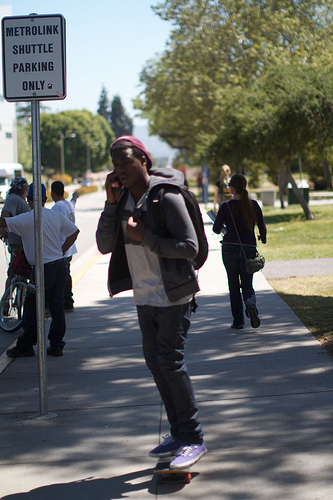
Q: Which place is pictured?
A: It is a sidewalk.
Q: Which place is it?
A: It is a sidewalk.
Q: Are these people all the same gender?
A: No, they are both male and female.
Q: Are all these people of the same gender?
A: No, they are both male and female.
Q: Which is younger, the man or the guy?
A: The man is younger than the guy.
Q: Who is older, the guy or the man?
A: The guy is older than the man.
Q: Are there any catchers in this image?
A: No, there are no catchers.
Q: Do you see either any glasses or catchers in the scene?
A: No, there are no catchers or glasses.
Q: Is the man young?
A: Yes, the man is young.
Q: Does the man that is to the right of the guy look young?
A: Yes, the man is young.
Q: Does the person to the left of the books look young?
A: Yes, the man is young.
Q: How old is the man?
A: The man is young.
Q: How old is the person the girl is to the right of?
A: The man is young.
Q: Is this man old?
A: No, the man is young.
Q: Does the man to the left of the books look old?
A: No, the man is young.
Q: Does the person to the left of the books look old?
A: No, the man is young.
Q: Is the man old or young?
A: The man is young.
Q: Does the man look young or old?
A: The man is young.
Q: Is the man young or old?
A: The man is young.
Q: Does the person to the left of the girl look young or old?
A: The man is young.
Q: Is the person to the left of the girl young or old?
A: The man is young.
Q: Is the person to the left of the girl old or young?
A: The man is young.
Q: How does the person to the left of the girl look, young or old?
A: The man is young.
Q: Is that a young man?
A: Yes, that is a young man.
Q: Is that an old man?
A: No, that is a young man.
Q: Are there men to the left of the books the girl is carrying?
A: Yes, there is a man to the left of the books.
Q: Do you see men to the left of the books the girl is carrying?
A: Yes, there is a man to the left of the books.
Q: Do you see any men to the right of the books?
A: No, the man is to the left of the books.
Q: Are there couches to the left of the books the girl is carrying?
A: No, there is a man to the left of the books.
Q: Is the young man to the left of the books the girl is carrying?
A: Yes, the man is to the left of the books.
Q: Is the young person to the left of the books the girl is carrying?
A: Yes, the man is to the left of the books.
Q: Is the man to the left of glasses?
A: No, the man is to the left of the books.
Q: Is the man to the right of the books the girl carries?
A: No, the man is to the left of the books.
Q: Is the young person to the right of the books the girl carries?
A: No, the man is to the left of the books.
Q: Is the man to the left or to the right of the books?
A: The man is to the left of the books.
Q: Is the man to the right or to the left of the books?
A: The man is to the left of the books.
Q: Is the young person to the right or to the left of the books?
A: The man is to the left of the books.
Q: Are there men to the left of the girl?
A: Yes, there is a man to the left of the girl.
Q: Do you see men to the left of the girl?
A: Yes, there is a man to the left of the girl.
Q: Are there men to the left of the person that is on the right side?
A: Yes, there is a man to the left of the girl.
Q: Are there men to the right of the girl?
A: No, the man is to the left of the girl.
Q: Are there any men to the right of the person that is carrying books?
A: No, the man is to the left of the girl.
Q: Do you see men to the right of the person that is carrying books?
A: No, the man is to the left of the girl.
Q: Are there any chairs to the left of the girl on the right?
A: No, there is a man to the left of the girl.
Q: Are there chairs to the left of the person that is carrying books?
A: No, there is a man to the left of the girl.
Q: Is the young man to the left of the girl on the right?
A: Yes, the man is to the left of the girl.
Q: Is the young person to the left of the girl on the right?
A: Yes, the man is to the left of the girl.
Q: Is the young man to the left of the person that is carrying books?
A: Yes, the man is to the left of the girl.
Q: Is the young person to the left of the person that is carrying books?
A: Yes, the man is to the left of the girl.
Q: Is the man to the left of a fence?
A: No, the man is to the left of the girl.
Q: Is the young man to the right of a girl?
A: No, the man is to the left of a girl.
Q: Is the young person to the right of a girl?
A: No, the man is to the left of a girl.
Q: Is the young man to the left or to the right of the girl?
A: The man is to the left of the girl.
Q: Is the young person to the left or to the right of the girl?
A: The man is to the left of the girl.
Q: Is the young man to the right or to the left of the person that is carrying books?
A: The man is to the left of the girl.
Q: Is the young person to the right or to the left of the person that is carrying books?
A: The man is to the left of the girl.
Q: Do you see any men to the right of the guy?
A: Yes, there is a man to the right of the guy.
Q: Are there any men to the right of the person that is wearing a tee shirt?
A: Yes, there is a man to the right of the guy.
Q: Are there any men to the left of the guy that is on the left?
A: No, the man is to the right of the guy.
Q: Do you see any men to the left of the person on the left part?
A: No, the man is to the right of the guy.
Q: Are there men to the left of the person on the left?
A: No, the man is to the right of the guy.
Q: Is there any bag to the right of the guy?
A: No, there is a man to the right of the guy.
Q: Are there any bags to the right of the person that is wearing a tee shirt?
A: No, there is a man to the right of the guy.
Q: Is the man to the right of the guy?
A: Yes, the man is to the right of the guy.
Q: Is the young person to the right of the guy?
A: Yes, the man is to the right of the guy.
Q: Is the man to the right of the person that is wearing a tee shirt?
A: Yes, the man is to the right of the guy.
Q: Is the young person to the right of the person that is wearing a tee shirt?
A: Yes, the man is to the right of the guy.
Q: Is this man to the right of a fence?
A: No, the man is to the right of the guy.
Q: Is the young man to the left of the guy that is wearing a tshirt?
A: No, the man is to the right of the guy.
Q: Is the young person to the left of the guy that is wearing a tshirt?
A: No, the man is to the right of the guy.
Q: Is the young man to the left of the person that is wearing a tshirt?
A: No, the man is to the right of the guy.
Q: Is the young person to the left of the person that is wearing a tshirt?
A: No, the man is to the right of the guy.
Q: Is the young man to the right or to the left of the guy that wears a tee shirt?
A: The man is to the right of the guy.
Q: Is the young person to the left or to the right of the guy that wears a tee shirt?
A: The man is to the right of the guy.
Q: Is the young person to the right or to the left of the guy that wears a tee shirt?
A: The man is to the right of the guy.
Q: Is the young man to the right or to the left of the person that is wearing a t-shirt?
A: The man is to the right of the guy.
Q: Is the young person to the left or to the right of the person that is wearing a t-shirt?
A: The man is to the right of the guy.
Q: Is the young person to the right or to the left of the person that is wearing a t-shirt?
A: The man is to the right of the guy.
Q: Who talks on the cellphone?
A: The man talks on the cellphone.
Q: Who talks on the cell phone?
A: The man talks on the cellphone.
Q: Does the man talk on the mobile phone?
A: Yes, the man talks on the mobile phone.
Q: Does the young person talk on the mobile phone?
A: Yes, the man talks on the mobile phone.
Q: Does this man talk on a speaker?
A: No, the man talks on the mobile phone.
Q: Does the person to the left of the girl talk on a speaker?
A: No, the man talks on the mobile phone.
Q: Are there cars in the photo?
A: No, there are no cars.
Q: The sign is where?
A: The sign is on the sidewalk.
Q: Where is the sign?
A: The sign is on the sidewalk.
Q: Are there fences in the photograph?
A: No, there are no fences.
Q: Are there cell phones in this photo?
A: Yes, there is a cell phone.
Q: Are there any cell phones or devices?
A: Yes, there is a cell phone.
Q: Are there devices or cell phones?
A: Yes, there is a cell phone.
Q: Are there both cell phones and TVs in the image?
A: No, there is a cell phone but no televisions.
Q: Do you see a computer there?
A: No, there are no computers.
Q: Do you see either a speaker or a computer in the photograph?
A: No, there are no computers or speakers.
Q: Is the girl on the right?
A: Yes, the girl is on the right of the image.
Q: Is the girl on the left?
A: No, the girl is on the right of the image.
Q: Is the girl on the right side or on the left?
A: The girl is on the right of the image.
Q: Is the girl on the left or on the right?
A: The girl is on the right of the image.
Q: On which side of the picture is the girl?
A: The girl is on the right of the image.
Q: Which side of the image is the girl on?
A: The girl is on the right of the image.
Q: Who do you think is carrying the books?
A: The girl is carrying the books.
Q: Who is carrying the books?
A: The girl is carrying the books.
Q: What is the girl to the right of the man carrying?
A: The girl is carrying books.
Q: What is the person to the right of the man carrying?
A: The girl is carrying books.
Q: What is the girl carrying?
A: The girl is carrying books.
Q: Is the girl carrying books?
A: Yes, the girl is carrying books.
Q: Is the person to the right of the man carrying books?
A: Yes, the girl is carrying books.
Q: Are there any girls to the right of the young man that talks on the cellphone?
A: Yes, there is a girl to the right of the man.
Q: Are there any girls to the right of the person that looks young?
A: Yes, there is a girl to the right of the man.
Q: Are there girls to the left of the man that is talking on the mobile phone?
A: No, the girl is to the right of the man.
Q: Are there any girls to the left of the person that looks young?
A: No, the girl is to the right of the man.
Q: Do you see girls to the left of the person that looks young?
A: No, the girl is to the right of the man.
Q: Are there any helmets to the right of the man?
A: No, there is a girl to the right of the man.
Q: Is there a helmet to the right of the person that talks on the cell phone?
A: No, there is a girl to the right of the man.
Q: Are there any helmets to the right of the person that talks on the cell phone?
A: No, there is a girl to the right of the man.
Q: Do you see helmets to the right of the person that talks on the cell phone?
A: No, there is a girl to the right of the man.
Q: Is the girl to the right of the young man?
A: Yes, the girl is to the right of the man.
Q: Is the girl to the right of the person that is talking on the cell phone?
A: Yes, the girl is to the right of the man.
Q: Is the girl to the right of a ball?
A: No, the girl is to the right of the man.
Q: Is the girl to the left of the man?
A: No, the girl is to the right of the man.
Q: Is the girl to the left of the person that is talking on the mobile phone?
A: No, the girl is to the right of the man.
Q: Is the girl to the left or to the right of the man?
A: The girl is to the right of the man.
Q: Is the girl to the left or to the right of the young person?
A: The girl is to the right of the man.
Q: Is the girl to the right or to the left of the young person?
A: The girl is to the right of the man.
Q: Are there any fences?
A: No, there are no fences.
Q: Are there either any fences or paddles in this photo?
A: No, there are no fences or paddles.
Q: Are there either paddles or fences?
A: No, there are no fences or paddles.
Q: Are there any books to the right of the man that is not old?
A: Yes, there are books to the right of the man.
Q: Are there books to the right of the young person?
A: Yes, there are books to the right of the man.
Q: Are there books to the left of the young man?
A: No, the books are to the right of the man.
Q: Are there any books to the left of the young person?
A: No, the books are to the right of the man.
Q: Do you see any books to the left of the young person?
A: No, the books are to the right of the man.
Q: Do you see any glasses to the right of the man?
A: No, there are books to the right of the man.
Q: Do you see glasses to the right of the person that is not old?
A: No, there are books to the right of the man.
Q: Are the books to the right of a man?
A: Yes, the books are to the right of a man.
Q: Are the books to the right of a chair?
A: No, the books are to the right of a man.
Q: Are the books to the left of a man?
A: No, the books are to the right of a man.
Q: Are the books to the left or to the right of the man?
A: The books are to the right of the man.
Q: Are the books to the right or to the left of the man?
A: The books are to the right of the man.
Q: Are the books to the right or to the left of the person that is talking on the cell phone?
A: The books are to the right of the man.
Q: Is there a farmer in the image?
A: No, there are no farmers.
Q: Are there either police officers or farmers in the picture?
A: No, there are no farmers or police officers.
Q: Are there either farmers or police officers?
A: No, there are no farmers or police officers.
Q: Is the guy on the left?
A: Yes, the guy is on the left of the image.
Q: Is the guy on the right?
A: No, the guy is on the left of the image.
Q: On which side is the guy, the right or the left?
A: The guy is on the left of the image.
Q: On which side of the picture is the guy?
A: The guy is on the left of the image.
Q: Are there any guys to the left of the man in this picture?
A: Yes, there is a guy to the left of the man.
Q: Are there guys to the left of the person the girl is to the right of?
A: Yes, there is a guy to the left of the man.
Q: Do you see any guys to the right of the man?
A: No, the guy is to the left of the man.